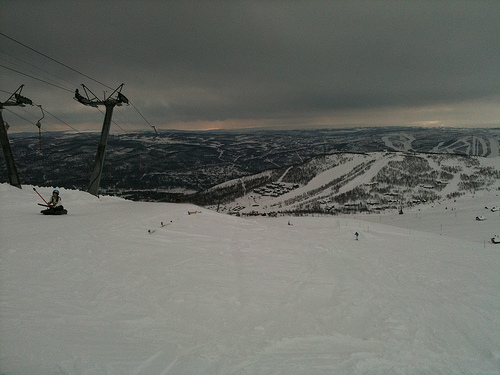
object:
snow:
[2, 179, 492, 371]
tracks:
[133, 217, 433, 357]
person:
[40, 190, 68, 215]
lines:
[0, 31, 160, 154]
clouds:
[2, 78, 498, 129]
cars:
[254, 180, 300, 198]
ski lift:
[0, 31, 159, 198]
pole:
[75, 88, 130, 197]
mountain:
[0, 151, 500, 370]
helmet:
[53, 189, 60, 195]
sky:
[0, 0, 499, 134]